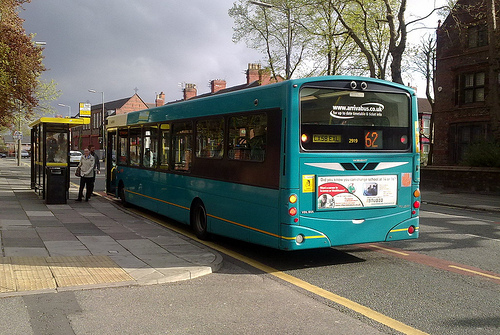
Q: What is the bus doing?
A: Dropping people off.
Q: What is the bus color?
A: Turquoise.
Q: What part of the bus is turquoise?
A: Back.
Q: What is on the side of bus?
A: Passenger window.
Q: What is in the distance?
A: Tall trees.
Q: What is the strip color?
A: Yellow.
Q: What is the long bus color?
A: Green.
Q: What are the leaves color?
A: Brown and green.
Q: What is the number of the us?
A: 62.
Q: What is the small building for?
A: Bus stop.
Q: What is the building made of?
A: Brick.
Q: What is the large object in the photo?
A: Bus.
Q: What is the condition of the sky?
A: Cloudy.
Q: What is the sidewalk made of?
A: Stones.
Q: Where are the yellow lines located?
A: Street.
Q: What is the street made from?
A: Asphalt.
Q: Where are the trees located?
A: Behind bus.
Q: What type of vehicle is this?
A: A bus.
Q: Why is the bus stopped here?
A: To pick up passengers.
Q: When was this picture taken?
A: Daytime.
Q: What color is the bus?
A: Blue.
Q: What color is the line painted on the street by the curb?
A: Yellow.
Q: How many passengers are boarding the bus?
A: Two.